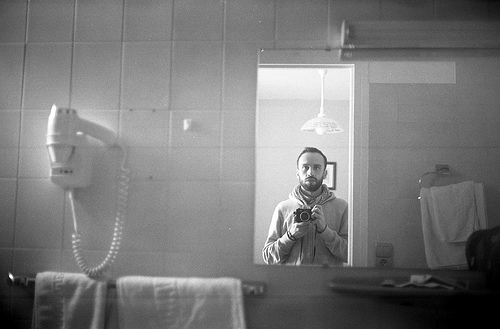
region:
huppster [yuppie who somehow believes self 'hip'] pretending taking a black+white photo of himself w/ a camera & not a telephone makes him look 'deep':
[258, 136, 348, 263]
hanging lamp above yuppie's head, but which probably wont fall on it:
[290, 68, 352, 140]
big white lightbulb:
[313, 127, 327, 137]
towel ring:
[413, 165, 455, 204]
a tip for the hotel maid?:
[371, 269, 465, 293]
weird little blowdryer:
[34, 100, 144, 283]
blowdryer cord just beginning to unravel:
[61, 145, 141, 282]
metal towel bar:
[1, 265, 270, 303]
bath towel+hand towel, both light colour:
[26, 265, 248, 327]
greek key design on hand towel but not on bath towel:
[45, 270, 70, 327]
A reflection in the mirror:
[268, 149, 349, 263]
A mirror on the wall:
[257, 50, 352, 261]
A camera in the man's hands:
[296, 208, 313, 220]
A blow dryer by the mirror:
[43, 104, 131, 279]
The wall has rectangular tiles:
[123, 40, 225, 242]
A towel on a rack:
[119, 281, 239, 326]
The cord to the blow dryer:
[101, 165, 138, 252]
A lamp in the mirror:
[309, 73, 337, 135]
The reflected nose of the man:
[308, 165, 313, 175]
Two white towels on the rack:
[41, 276, 237, 321]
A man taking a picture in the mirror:
[260, 146, 345, 262]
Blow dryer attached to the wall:
[45, 105, 130, 275]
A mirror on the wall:
[251, 48, 497, 264]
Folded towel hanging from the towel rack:
[22, 271, 108, 327]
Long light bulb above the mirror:
[341, 18, 498, 48]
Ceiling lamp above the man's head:
[302, 68, 342, 134]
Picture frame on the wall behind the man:
[321, 160, 337, 190]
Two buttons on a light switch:
[375, 243, 392, 265]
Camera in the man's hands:
[292, 207, 317, 222]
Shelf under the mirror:
[328, 275, 483, 302]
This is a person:
[261, 131, 357, 271]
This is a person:
[304, 160, 364, 247]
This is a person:
[260, 195, 320, 272]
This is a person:
[280, 139, 339, 219]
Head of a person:
[294, 133, 335, 196]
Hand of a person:
[314, 197, 351, 264]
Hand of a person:
[261, 195, 314, 270]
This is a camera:
[294, 205, 320, 222]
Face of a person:
[299, 155, 322, 187]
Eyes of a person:
[299, 160, 321, 173]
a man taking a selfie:
[242, 57, 374, 269]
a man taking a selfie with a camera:
[258, 59, 358, 276]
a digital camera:
[282, 200, 329, 231]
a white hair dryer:
[28, 91, 145, 279]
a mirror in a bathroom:
[232, 42, 492, 303]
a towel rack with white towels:
[9, 262, 270, 327]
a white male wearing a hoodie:
[261, 143, 356, 277]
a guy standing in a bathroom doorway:
[264, 130, 356, 259]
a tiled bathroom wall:
[142, 0, 234, 253]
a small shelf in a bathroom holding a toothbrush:
[317, 271, 474, 306]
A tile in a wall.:
[165, 106, 226, 148]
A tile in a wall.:
[165, 143, 222, 183]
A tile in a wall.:
[118, 105, 172, 145]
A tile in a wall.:
[113, 32, 168, 114]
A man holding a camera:
[255, 136, 353, 268]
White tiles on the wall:
[0, 0, 492, 325]